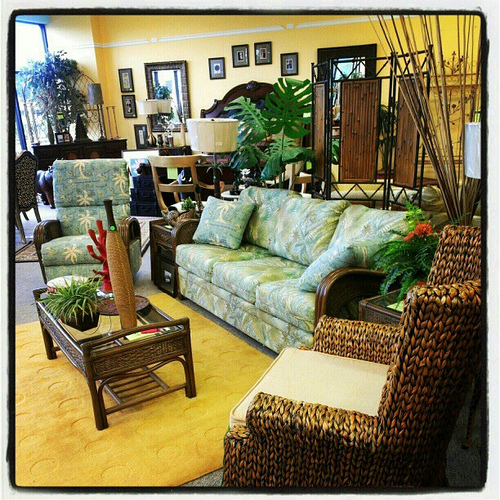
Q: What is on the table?
A: Flowers.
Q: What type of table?
A: Coffee table.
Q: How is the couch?
A: Three seat couch.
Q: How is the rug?
A: Thick and yellow.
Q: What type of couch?
A: Green palm tree.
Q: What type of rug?
A: A yellow rug.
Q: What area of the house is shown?
A: Living room.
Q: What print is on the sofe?
A: Tropical print.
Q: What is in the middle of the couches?
A: Table.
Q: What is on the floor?
A: Area rug.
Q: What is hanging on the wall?
A: Pictures.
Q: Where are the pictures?
A: On the wall.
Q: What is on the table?
A: Plant.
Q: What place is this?
A: Furniture store.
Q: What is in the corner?
A: Potted plant.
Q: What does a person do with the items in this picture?
A: Sit on them.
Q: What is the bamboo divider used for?
A: To divide up a room.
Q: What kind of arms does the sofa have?
A: Rattan arms.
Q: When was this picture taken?
A: During the day.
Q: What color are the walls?
A: Yellow.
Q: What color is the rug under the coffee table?
A: Yellow.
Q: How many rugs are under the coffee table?
A: One.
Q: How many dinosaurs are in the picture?
A: Zero.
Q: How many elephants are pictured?
A: Zero.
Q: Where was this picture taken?
A: Living room.